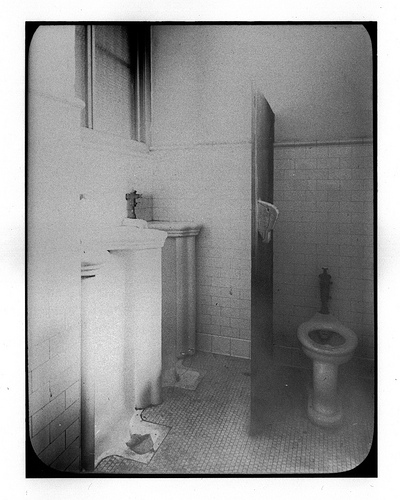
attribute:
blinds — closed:
[85, 29, 150, 147]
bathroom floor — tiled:
[179, 405, 241, 454]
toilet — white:
[294, 267, 359, 427]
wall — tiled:
[26, 20, 372, 474]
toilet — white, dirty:
[289, 299, 351, 427]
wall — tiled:
[269, 143, 370, 324]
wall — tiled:
[152, 150, 246, 360]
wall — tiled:
[152, 31, 365, 137]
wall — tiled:
[32, 107, 156, 405]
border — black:
[27, 22, 379, 477]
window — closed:
[70, 32, 158, 148]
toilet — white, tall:
[295, 288, 367, 444]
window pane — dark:
[85, 26, 151, 144]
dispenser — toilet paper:
[258, 196, 278, 255]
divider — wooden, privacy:
[232, 69, 292, 457]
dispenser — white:
[252, 195, 282, 246]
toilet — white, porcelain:
[283, 310, 373, 448]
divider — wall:
[238, 128, 266, 276]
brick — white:
[303, 189, 326, 199]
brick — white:
[340, 201, 362, 209]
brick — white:
[315, 242, 339, 254]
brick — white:
[318, 155, 339, 168]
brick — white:
[271, 158, 294, 168]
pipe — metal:
[318, 267, 332, 315]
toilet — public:
[279, 298, 367, 420]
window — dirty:
[75, 23, 145, 152]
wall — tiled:
[163, 42, 377, 381]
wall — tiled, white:
[28, 28, 170, 457]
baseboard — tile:
[192, 328, 274, 358]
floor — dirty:
[93, 349, 376, 477]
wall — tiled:
[146, 23, 373, 364]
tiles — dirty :
[112, 350, 379, 470]